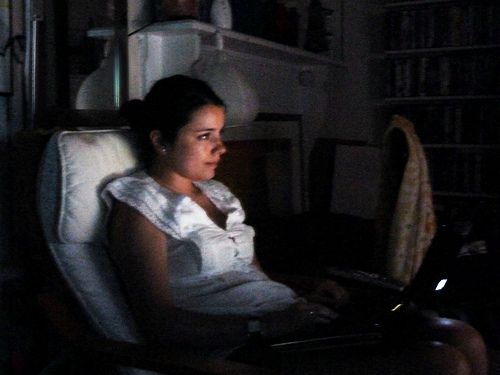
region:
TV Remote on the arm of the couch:
[319, 260, 407, 296]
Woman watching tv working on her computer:
[116, 75, 498, 372]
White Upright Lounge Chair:
[33, 113, 334, 371]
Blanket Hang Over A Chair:
[381, 112, 438, 294]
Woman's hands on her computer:
[263, 275, 363, 350]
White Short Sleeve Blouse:
[100, 177, 312, 326]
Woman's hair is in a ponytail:
[110, 74, 238, 191]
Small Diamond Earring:
[160, 147, 165, 154]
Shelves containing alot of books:
[358, 4, 493, 215]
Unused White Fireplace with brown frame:
[187, 107, 315, 254]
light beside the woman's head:
[195, 46, 262, 140]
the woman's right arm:
[101, 209, 171, 306]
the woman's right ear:
[145, 129, 170, 160]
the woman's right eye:
[195, 127, 211, 143]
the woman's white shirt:
[104, 164, 309, 329]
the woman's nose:
[210, 143, 230, 158]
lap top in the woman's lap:
[258, 262, 456, 357]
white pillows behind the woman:
[26, 127, 155, 356]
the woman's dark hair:
[118, 69, 226, 167]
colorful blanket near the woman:
[364, 107, 444, 299]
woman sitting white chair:
[97, 75, 458, 347]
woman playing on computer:
[71, 85, 453, 365]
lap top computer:
[310, 222, 485, 337]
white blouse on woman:
[98, 168, 282, 328]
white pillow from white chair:
[51, 125, 131, 240]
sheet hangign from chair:
[344, 114, 449, 269]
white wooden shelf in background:
[144, 23, 326, 65]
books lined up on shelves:
[372, 25, 494, 112]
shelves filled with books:
[372, 13, 482, 115]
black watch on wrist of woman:
[238, 308, 269, 345]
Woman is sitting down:
[94, 71, 474, 366]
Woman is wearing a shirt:
[101, 170, 301, 312]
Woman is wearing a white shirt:
[102, 167, 307, 324]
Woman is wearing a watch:
[241, 306, 266, 341]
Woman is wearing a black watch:
[240, 305, 261, 342]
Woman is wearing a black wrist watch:
[240, 305, 261, 340]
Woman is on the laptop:
[251, 217, 478, 356]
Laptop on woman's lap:
[257, 218, 463, 357]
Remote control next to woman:
[320, 260, 405, 296]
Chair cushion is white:
[42, 119, 183, 372]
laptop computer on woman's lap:
[333, 215, 475, 330]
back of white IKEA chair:
[33, 123, 141, 373]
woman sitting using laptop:
[99, 67, 492, 373]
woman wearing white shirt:
[98, 63, 490, 373]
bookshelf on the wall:
[380, 0, 498, 221]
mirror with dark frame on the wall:
[52, 0, 129, 126]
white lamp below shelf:
[201, 52, 261, 134]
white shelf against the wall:
[139, 17, 351, 77]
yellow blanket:
[384, 116, 441, 288]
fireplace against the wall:
[216, 106, 313, 218]